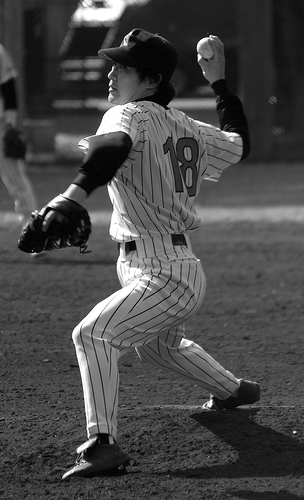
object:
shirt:
[94, 96, 243, 261]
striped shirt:
[110, 143, 203, 264]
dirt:
[3, 167, 303, 499]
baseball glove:
[18, 192, 94, 254]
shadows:
[155, 408, 304, 500]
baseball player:
[18, 28, 262, 480]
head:
[96, 30, 177, 108]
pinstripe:
[88, 348, 118, 430]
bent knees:
[63, 259, 206, 394]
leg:
[71, 283, 191, 442]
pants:
[71, 249, 238, 438]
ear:
[146, 73, 163, 89]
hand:
[196, 34, 226, 84]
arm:
[194, 78, 251, 181]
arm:
[67, 104, 134, 200]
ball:
[196, 36, 214, 60]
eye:
[120, 63, 128, 71]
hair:
[153, 75, 177, 104]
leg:
[134, 324, 239, 399]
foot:
[60, 436, 130, 485]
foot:
[200, 376, 261, 413]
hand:
[32, 195, 83, 258]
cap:
[97, 27, 178, 79]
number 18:
[162, 135, 198, 197]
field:
[0, 240, 304, 422]